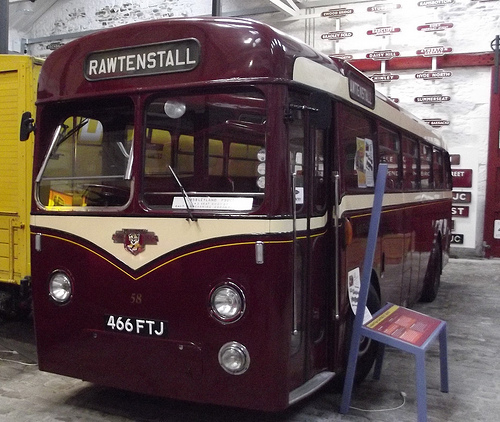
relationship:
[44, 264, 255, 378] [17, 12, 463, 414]
headlights on bu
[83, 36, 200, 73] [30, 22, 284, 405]
sign on bus front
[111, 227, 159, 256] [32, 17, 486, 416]
symbol on front of bus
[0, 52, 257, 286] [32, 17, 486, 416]
car visible beside bus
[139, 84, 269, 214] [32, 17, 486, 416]
front window on bus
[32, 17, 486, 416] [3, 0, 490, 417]
bus parked in garage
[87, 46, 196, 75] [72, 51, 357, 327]
title on front of bus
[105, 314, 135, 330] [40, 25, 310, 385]
numbers on front of bus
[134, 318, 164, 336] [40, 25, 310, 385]
letters on front of bus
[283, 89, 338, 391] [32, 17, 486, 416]
door of bus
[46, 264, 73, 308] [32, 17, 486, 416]
headlight of bus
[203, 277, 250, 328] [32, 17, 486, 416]
headlight of bus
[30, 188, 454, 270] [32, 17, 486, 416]
stripe on bus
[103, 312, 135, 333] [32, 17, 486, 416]
numbers on bus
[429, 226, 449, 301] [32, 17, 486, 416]
tire to bus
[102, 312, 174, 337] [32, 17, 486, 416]
numbers on bus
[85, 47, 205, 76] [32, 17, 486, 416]
letters on bus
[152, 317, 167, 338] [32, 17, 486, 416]
letter on bus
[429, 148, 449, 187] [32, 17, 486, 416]
windows on bus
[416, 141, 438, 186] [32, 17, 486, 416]
windows on bus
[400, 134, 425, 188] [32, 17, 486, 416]
windows on bus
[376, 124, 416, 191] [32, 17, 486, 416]
windows on bus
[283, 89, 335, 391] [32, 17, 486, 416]
door on side of bus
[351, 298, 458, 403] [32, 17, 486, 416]
item next to bus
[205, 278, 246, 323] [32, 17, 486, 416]
headlight on bus